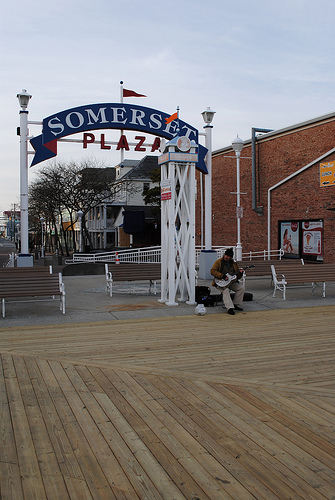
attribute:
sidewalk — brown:
[5, 307, 334, 497]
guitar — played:
[213, 261, 257, 290]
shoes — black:
[225, 302, 242, 313]